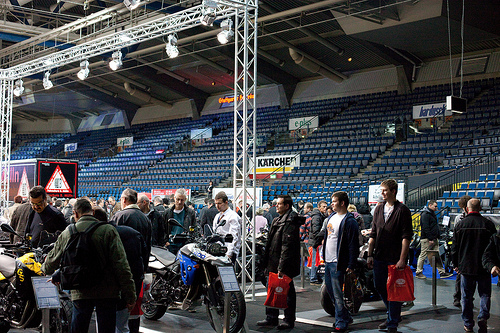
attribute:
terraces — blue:
[2, 87, 497, 194]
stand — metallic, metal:
[265, 175, 387, 211]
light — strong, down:
[162, 41, 185, 56]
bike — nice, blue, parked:
[147, 226, 251, 332]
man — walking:
[368, 174, 419, 331]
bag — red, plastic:
[383, 265, 415, 306]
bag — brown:
[336, 263, 370, 316]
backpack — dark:
[57, 236, 107, 293]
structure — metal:
[1, 3, 259, 205]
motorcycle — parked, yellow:
[2, 218, 66, 332]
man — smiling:
[257, 191, 305, 331]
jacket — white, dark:
[262, 211, 308, 279]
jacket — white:
[206, 208, 247, 256]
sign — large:
[246, 151, 303, 182]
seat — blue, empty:
[485, 190, 500, 207]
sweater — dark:
[324, 212, 362, 274]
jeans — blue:
[320, 264, 352, 328]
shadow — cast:
[360, 302, 457, 328]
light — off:
[40, 74, 57, 92]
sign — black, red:
[37, 158, 82, 201]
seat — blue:
[488, 172, 497, 180]